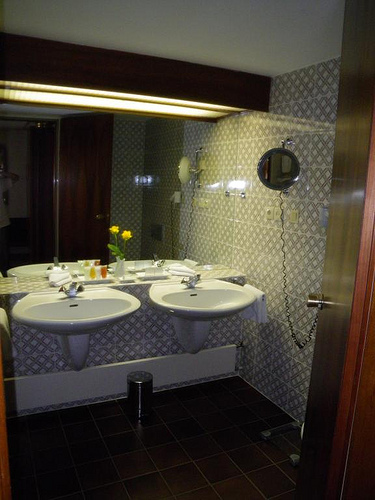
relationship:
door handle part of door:
[305, 294, 336, 309] [298, 5, 374, 495]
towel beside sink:
[242, 276, 278, 342] [144, 280, 258, 353]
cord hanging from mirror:
[272, 193, 315, 352] [256, 148, 304, 193]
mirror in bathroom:
[1, 94, 240, 289] [4, 7, 374, 499]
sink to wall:
[144, 280, 258, 353] [4, 60, 275, 411]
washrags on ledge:
[48, 272, 72, 287] [0, 263, 243, 296]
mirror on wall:
[253, 148, 301, 191] [0, 58, 338, 426]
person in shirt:
[0, 158, 21, 267] [0, 178, 14, 228]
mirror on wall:
[1, 94, 240, 289] [3, 33, 260, 398]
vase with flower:
[112, 253, 127, 283] [104, 220, 131, 259]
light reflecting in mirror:
[201, 167, 248, 216] [0, 84, 257, 274]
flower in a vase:
[118, 228, 137, 258] [110, 248, 131, 285]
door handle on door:
[305, 294, 336, 309] [303, 106, 363, 438]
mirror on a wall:
[253, 148, 301, 191] [238, 213, 275, 262]